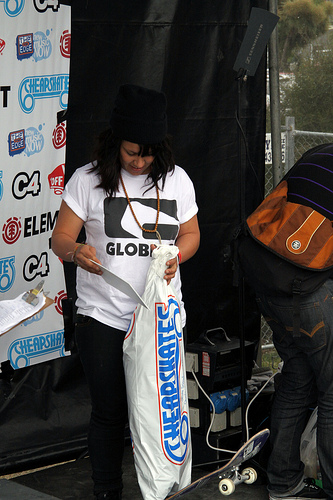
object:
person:
[244, 144, 332, 500]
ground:
[283, 79, 305, 111]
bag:
[122, 243, 192, 500]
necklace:
[117, 171, 160, 233]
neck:
[120, 165, 152, 175]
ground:
[229, 101, 262, 142]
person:
[51, 87, 203, 500]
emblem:
[7, 128, 26, 157]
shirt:
[60, 158, 198, 332]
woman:
[50, 87, 201, 500]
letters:
[154, 294, 189, 465]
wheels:
[241, 466, 257, 484]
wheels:
[218, 477, 236, 496]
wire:
[184, 327, 246, 468]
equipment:
[64, 0, 279, 454]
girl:
[49, 87, 200, 500]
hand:
[148, 244, 178, 286]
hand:
[73, 244, 103, 275]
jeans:
[255, 279, 332, 499]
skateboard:
[162, 428, 271, 499]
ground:
[2, 461, 78, 497]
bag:
[243, 181, 333, 271]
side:
[0, 0, 62, 500]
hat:
[110, 83, 169, 138]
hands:
[72, 244, 178, 287]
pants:
[73, 311, 128, 500]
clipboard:
[0, 288, 47, 335]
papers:
[0, 289, 46, 336]